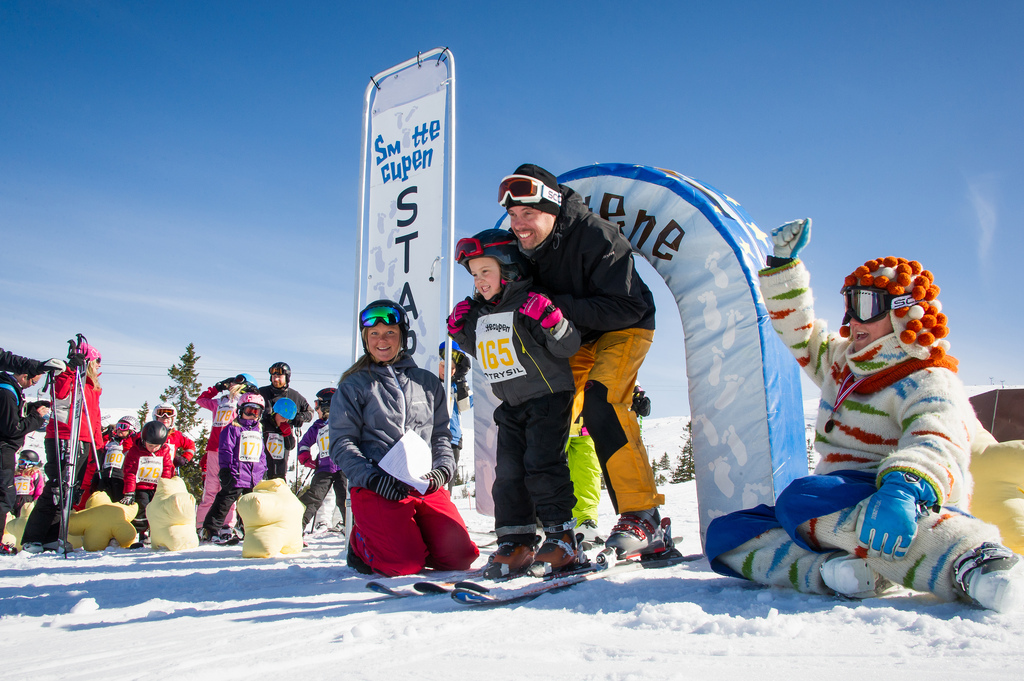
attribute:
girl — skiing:
[384, 259, 696, 676]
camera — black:
[33, 361, 152, 558]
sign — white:
[289, 190, 722, 510]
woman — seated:
[311, 276, 512, 460]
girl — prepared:
[452, 276, 496, 326]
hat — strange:
[795, 259, 1005, 380]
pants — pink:
[290, 428, 502, 588]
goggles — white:
[473, 145, 573, 243]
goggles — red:
[376, 183, 690, 350]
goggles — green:
[335, 268, 424, 335]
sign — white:
[443, 259, 591, 387]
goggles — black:
[734, 224, 953, 415]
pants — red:
[320, 445, 509, 562]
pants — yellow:
[536, 281, 630, 474]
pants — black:
[451, 417, 653, 536]